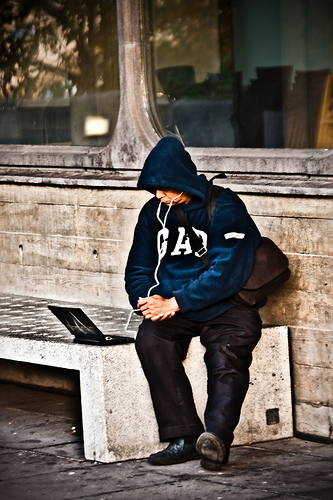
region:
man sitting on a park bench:
[124, 135, 289, 469]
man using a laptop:
[124, 136, 289, 468]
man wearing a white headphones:
[124, 139, 290, 470]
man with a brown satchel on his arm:
[124, 132, 259, 470]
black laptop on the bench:
[48, 306, 134, 346]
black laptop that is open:
[48, 306, 132, 346]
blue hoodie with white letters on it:
[122, 137, 259, 320]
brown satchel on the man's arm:
[174, 183, 291, 310]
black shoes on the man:
[146, 431, 230, 470]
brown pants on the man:
[134, 305, 262, 444]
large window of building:
[143, 3, 331, 151]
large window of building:
[0, 0, 124, 155]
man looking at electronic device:
[40, 146, 224, 338]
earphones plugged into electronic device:
[38, 189, 174, 348]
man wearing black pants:
[129, 303, 266, 430]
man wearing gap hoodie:
[120, 137, 264, 321]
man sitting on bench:
[70, 126, 294, 461]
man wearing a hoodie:
[122, 134, 257, 324]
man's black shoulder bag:
[194, 171, 294, 308]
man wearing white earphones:
[154, 186, 183, 239]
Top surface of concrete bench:
[6, 309, 45, 332]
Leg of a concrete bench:
[118, 391, 147, 428]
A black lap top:
[78, 336, 94, 340]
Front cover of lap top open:
[59, 311, 67, 314]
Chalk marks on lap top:
[76, 323, 81, 332]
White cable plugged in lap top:
[128, 321, 129, 322]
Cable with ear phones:
[162, 225, 164, 226]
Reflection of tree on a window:
[63, 16, 83, 33]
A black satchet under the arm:
[255, 262, 271, 283]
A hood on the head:
[147, 169, 171, 181]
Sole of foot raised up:
[202, 439, 216, 455]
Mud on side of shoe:
[158, 462, 168, 463]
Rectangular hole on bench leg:
[269, 413, 275, 421]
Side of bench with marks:
[271, 368, 285, 391]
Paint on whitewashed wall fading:
[45, 212, 84, 234]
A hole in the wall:
[93, 251, 95, 252]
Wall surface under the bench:
[16, 368, 43, 380]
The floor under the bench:
[10, 391, 29, 404]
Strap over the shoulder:
[209, 194, 211, 205]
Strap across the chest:
[186, 224, 189, 227]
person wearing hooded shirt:
[98, 126, 274, 330]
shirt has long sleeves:
[110, 125, 260, 336]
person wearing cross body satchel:
[153, 169, 303, 322]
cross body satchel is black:
[137, 180, 309, 317]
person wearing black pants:
[111, 282, 270, 451]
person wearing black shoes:
[136, 424, 239, 471]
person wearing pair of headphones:
[125, 175, 181, 329]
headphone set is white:
[133, 189, 180, 342]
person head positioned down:
[123, 157, 218, 222]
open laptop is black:
[39, 288, 143, 366]